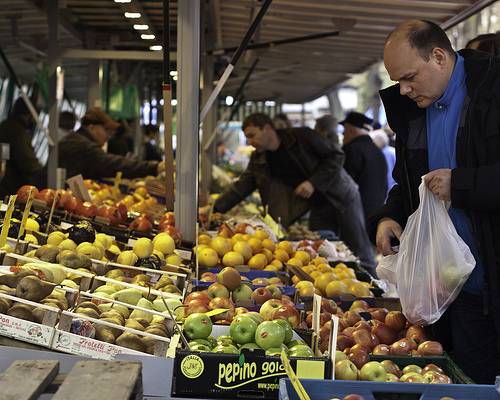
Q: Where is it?
A: This is at the market.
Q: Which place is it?
A: It is a market.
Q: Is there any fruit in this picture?
A: Yes, there is a fruit.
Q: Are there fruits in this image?
A: Yes, there is a fruit.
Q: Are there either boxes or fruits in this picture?
A: Yes, there is a fruit.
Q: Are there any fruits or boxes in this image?
A: Yes, there is a fruit.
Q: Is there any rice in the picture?
A: No, there is no rice.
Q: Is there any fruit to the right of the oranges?
A: Yes, there is a fruit to the right of the oranges.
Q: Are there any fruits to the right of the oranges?
A: Yes, there is a fruit to the right of the oranges.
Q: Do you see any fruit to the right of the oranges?
A: Yes, there is a fruit to the right of the oranges.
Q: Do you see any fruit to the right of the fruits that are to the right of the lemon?
A: Yes, there is a fruit to the right of the oranges.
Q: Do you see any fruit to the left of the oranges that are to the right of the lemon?
A: No, the fruit is to the right of the oranges.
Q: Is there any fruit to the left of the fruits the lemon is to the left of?
A: No, the fruit is to the right of the oranges.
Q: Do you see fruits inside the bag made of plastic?
A: Yes, there is a fruit inside the bag.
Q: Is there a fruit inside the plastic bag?
A: Yes, there is a fruit inside the bag.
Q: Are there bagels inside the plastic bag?
A: No, there is a fruit inside the bag.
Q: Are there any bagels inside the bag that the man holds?
A: No, there is a fruit inside the bag.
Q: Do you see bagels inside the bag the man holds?
A: No, there is a fruit inside the bag.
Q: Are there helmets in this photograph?
A: No, there are no helmets.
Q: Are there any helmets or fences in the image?
A: No, there are no helmets or fences.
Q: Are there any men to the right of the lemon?
A: Yes, there is a man to the right of the lemon.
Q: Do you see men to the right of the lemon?
A: Yes, there is a man to the right of the lemon.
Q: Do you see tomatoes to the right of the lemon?
A: No, there is a man to the right of the lemon.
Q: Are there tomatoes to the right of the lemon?
A: No, there is a man to the right of the lemon.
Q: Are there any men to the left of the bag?
A: Yes, there is a man to the left of the bag.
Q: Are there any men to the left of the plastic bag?
A: Yes, there is a man to the left of the bag.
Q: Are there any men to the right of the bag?
A: No, the man is to the left of the bag.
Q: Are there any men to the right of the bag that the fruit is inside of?
A: No, the man is to the left of the bag.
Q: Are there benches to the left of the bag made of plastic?
A: No, there is a man to the left of the bag.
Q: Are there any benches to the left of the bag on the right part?
A: No, there is a man to the left of the bag.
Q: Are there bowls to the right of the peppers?
A: No, there is a man to the right of the peppers.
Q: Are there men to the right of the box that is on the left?
A: Yes, there is a man to the right of the box.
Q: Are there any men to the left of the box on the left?
A: No, the man is to the right of the box.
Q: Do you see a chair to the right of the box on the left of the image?
A: No, there is a man to the right of the box.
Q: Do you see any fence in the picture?
A: No, there are no fences.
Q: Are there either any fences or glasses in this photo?
A: No, there are no fences or glasses.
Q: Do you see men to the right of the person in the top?
A: Yes, there is a man to the right of the person.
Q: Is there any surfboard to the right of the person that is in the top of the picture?
A: No, there is a man to the right of the person.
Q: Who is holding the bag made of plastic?
A: The man is holding the bag.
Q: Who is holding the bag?
A: The man is holding the bag.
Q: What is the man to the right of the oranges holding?
A: The man is holding the bag.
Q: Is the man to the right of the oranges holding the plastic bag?
A: Yes, the man is holding the bag.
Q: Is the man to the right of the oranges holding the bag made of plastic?
A: Yes, the man is holding the bag.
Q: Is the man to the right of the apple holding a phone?
A: No, the man is holding the bag.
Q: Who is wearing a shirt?
A: The man is wearing a shirt.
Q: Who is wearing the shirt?
A: The man is wearing a shirt.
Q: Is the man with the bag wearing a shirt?
A: Yes, the man is wearing a shirt.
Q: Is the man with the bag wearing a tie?
A: No, the man is wearing a shirt.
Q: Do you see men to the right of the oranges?
A: Yes, there is a man to the right of the oranges.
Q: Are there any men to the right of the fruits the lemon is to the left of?
A: Yes, there is a man to the right of the oranges.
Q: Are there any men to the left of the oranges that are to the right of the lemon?
A: No, the man is to the right of the oranges.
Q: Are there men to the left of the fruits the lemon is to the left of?
A: No, the man is to the right of the oranges.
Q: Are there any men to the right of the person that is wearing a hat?
A: Yes, there is a man to the right of the person.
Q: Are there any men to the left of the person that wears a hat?
A: No, the man is to the right of the person.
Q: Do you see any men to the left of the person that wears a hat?
A: No, the man is to the right of the person.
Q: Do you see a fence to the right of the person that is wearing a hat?
A: No, there is a man to the right of the person.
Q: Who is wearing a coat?
A: The man is wearing a coat.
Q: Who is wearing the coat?
A: The man is wearing a coat.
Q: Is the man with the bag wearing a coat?
A: Yes, the man is wearing a coat.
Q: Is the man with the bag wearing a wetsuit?
A: No, the man is wearing a coat.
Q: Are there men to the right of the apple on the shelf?
A: Yes, there is a man to the right of the apple.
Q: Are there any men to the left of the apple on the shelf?
A: No, the man is to the right of the apple.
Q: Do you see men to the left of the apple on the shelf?
A: No, the man is to the right of the apple.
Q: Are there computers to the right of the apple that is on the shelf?
A: No, there is a man to the right of the apple.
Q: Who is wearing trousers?
A: The man is wearing trousers.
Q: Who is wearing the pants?
A: The man is wearing trousers.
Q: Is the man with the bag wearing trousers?
A: Yes, the man is wearing trousers.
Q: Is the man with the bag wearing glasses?
A: No, the man is wearing trousers.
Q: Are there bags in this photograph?
A: Yes, there is a bag.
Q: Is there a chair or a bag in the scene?
A: Yes, there is a bag.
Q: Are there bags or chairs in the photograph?
A: Yes, there is a bag.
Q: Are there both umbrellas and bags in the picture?
A: No, there is a bag but no umbrellas.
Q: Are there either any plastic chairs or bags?
A: Yes, there is a plastic bag.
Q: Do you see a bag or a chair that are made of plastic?
A: Yes, the bag is made of plastic.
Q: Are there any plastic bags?
A: Yes, there is a bag that is made of plastic.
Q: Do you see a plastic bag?
A: Yes, there is a bag that is made of plastic.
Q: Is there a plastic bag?
A: Yes, there is a bag that is made of plastic.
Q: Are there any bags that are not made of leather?
A: Yes, there is a bag that is made of plastic.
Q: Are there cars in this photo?
A: No, there are no cars.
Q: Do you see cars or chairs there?
A: No, there are no cars or chairs.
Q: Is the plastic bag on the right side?
A: Yes, the bag is on the right of the image.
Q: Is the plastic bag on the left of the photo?
A: No, the bag is on the right of the image.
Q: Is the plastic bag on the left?
A: No, the bag is on the right of the image.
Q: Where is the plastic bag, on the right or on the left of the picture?
A: The bag is on the right of the image.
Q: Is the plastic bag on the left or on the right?
A: The bag is on the right of the image.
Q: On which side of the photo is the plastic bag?
A: The bag is on the right of the image.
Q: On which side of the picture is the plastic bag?
A: The bag is on the right of the image.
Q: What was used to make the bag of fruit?
A: The bag is made of plastic.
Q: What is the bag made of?
A: The bag is made of plastic.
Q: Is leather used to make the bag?
A: No, the bag is made of plastic.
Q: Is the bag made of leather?
A: No, the bag is made of plastic.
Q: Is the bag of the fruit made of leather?
A: No, the bag is made of plastic.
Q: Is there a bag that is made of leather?
A: No, there is a bag but it is made of plastic.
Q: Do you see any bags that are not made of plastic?
A: No, there is a bag but it is made of plastic.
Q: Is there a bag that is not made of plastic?
A: No, there is a bag but it is made of plastic.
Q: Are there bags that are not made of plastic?
A: No, there is a bag but it is made of plastic.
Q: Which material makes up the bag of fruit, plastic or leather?
A: The bag is made of plastic.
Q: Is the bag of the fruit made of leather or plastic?
A: The bag is made of plastic.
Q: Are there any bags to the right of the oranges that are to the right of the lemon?
A: Yes, there is a bag to the right of the oranges.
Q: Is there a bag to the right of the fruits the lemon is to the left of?
A: Yes, there is a bag to the right of the oranges.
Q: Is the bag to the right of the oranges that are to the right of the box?
A: Yes, the bag is to the right of the oranges.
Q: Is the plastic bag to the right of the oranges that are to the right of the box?
A: Yes, the bag is to the right of the oranges.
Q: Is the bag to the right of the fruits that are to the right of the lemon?
A: Yes, the bag is to the right of the oranges.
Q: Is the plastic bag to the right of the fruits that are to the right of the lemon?
A: Yes, the bag is to the right of the oranges.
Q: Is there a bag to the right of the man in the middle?
A: Yes, there is a bag to the right of the man.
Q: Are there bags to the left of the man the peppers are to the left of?
A: No, the bag is to the right of the man.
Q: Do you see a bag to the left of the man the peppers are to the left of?
A: No, the bag is to the right of the man.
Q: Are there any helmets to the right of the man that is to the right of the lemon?
A: No, there is a bag to the right of the man.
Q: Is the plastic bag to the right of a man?
A: Yes, the bag is to the right of a man.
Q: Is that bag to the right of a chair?
A: No, the bag is to the right of a man.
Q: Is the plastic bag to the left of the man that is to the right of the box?
A: No, the bag is to the right of the man.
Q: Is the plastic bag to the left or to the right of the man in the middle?
A: The bag is to the right of the man.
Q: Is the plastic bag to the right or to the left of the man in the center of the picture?
A: The bag is to the right of the man.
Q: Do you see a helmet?
A: No, there are no helmets.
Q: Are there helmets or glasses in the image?
A: No, there are no helmets or glasses.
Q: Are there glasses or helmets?
A: No, there are no helmets or glasses.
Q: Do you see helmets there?
A: No, there are no helmets.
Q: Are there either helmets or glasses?
A: No, there are no helmets or glasses.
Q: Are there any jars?
A: No, there are no jars.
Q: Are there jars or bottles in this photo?
A: No, there are no jars or bottles.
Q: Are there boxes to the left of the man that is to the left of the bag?
A: Yes, there is a box to the left of the man.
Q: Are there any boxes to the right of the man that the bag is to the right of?
A: No, the box is to the left of the man.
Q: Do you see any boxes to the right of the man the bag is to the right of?
A: No, the box is to the left of the man.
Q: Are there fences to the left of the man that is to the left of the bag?
A: No, there is a box to the left of the man.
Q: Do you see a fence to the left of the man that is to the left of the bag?
A: No, there is a box to the left of the man.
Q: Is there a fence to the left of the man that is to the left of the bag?
A: No, there is a box to the left of the man.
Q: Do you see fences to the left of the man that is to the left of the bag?
A: No, there is a box to the left of the man.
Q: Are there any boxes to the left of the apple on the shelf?
A: Yes, there is a box to the left of the apple.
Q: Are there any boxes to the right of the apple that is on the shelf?
A: No, the box is to the left of the apple.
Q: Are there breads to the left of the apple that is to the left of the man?
A: No, there is a box to the left of the apple.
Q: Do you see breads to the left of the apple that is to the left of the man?
A: No, there is a box to the left of the apple.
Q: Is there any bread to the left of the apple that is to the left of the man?
A: No, there is a box to the left of the apple.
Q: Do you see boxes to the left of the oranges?
A: Yes, there is a box to the left of the oranges.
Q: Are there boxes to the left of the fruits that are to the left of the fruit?
A: Yes, there is a box to the left of the oranges.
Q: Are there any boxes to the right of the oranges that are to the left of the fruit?
A: No, the box is to the left of the oranges.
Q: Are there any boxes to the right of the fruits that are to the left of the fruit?
A: No, the box is to the left of the oranges.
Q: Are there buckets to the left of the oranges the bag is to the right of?
A: No, there is a box to the left of the oranges.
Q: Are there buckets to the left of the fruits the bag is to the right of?
A: No, there is a box to the left of the oranges.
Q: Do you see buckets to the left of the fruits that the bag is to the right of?
A: No, there is a box to the left of the oranges.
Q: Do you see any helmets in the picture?
A: No, there are no helmets.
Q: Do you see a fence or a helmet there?
A: No, there are no helmets or fences.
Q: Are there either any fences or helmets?
A: No, there are no helmets or fences.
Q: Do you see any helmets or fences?
A: No, there are no helmets or fences.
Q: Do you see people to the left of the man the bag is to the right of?
A: Yes, there is a person to the left of the man.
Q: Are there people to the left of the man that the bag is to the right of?
A: Yes, there is a person to the left of the man.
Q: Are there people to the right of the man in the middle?
A: No, the person is to the left of the man.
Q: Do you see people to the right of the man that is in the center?
A: No, the person is to the left of the man.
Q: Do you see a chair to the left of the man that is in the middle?
A: No, there is a person to the left of the man.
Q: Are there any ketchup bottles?
A: No, there are no ketchup bottles.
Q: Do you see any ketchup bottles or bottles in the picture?
A: No, there are no ketchup bottles or bottles.